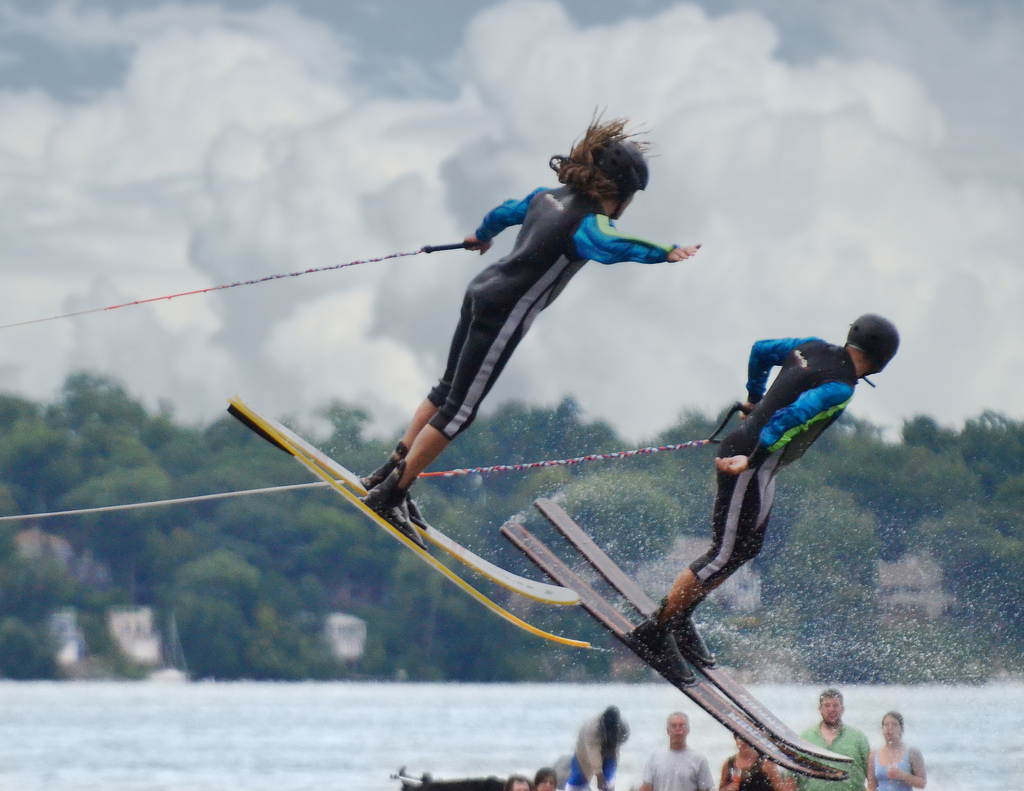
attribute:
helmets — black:
[592, 57, 915, 408]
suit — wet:
[654, 307, 922, 657]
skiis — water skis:
[4, 366, 597, 660]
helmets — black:
[560, 102, 904, 370]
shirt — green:
[793, 716, 873, 783]